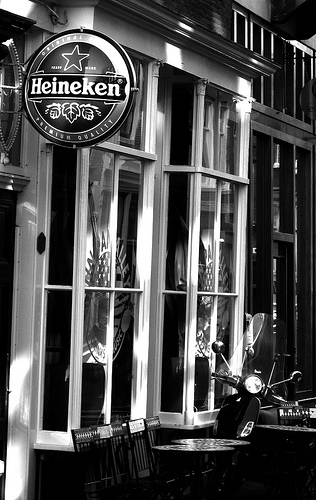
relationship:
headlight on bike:
[244, 375, 262, 395] [206, 309, 315, 456]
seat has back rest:
[71, 422, 146, 498] [69, 424, 123, 494]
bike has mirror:
[206, 309, 315, 456] [212, 338, 225, 352]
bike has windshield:
[206, 309, 315, 456] [220, 309, 298, 392]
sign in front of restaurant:
[21, 28, 137, 150] [0, 0, 314, 498]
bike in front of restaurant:
[206, 339, 314, 444] [0, 0, 314, 498]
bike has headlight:
[206, 339, 314, 444] [243, 374, 263, 394]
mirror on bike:
[211, 340, 227, 352] [206, 339, 314, 444]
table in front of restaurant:
[149, 442, 232, 499] [0, 0, 314, 498]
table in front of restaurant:
[149, 439, 252, 500] [0, 0, 314, 498]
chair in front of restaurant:
[119, 413, 163, 492] [0, 0, 314, 498]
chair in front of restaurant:
[68, 423, 131, 498] [0, 0, 314, 498]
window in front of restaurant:
[157, 64, 239, 415] [0, 0, 314, 498]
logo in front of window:
[82, 232, 135, 365] [73, 50, 153, 446]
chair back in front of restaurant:
[118, 412, 163, 486] [0, 0, 314, 498]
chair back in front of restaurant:
[68, 424, 127, 495] [0, 0, 314, 498]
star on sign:
[61, 43, 88, 73] [21, 28, 137, 150]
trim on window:
[193, 81, 251, 184] [200, 74, 246, 180]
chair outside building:
[70, 421, 125, 499] [1, 0, 314, 496]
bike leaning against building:
[206, 339, 314, 444] [1, 0, 314, 496]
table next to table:
[149, 439, 252, 500] [149, 442, 232, 499]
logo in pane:
[82, 227, 134, 364] [82, 147, 142, 431]